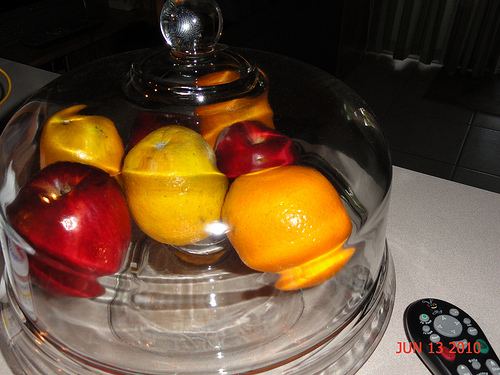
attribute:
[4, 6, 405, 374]
bowl — large, glass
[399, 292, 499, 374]
remote — black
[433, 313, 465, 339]
button — grey, four direction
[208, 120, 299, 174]
apple — red, covered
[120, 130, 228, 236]
orange — covered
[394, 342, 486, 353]
date — red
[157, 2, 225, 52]
top — round, glass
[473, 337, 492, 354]
button — green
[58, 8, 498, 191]
floor — tile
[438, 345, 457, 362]
button — red